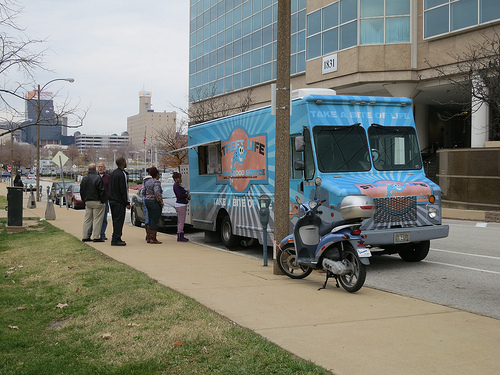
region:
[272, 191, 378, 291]
A blue motor scooter next to a food truck.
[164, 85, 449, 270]
A blue food truck near a tall building.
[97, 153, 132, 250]
a man wearing a black jacket.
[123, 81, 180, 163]
a very tall multi story building.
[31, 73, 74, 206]
a tall street light.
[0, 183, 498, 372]
a long paved sidewalk.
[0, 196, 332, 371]
a patch of dark green grass.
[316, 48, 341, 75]
a sign on the front of a building.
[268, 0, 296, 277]
a tall palm tree.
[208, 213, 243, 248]
the left rear tire.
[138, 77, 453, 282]
the truck is blue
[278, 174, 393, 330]
the bike is parked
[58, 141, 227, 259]
people are lining up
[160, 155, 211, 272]
woman is waiting for the food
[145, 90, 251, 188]
the trees are bare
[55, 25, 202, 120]
the sky is overcast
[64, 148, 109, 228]
two men are talking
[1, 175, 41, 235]
trash bin is black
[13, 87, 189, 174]
buildings in the distance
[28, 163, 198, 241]
the cars are parked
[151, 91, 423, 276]
blue bus with orange aand whtie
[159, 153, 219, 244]
woman at food truck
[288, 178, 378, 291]
blue moped on sidewalk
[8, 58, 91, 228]
lamp post on sidewalk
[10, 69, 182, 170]
city in background of photo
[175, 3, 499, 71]
green tinted window on building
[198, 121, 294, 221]
orange sign with advertisement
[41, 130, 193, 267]
people standing on side walk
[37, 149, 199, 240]
people waiting for food truck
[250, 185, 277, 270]
parking meter near food truck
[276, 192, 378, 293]
motorized scooter parked on sidewalk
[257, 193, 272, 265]
parking meter on sidewalk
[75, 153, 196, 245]
several people on line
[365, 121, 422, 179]
truck windshield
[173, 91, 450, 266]
blue food truck parked on road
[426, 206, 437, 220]
truck headlight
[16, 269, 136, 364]
section of grass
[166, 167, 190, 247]
woman with purple pants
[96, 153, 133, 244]
man with black jacket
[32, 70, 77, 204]
tall street lamp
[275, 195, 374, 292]
Scooter parked on the sidewalk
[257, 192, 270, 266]
Parking meter on the sidewalk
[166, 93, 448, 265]
Food cart on the street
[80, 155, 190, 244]
People standing on the sidewalk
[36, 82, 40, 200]
Light pole on the sidewalk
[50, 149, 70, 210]
Road sign on a stick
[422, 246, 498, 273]
White lines on the street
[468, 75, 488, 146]
White pillar in a building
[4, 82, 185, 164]
Buildings in distance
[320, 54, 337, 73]
Sign on the building